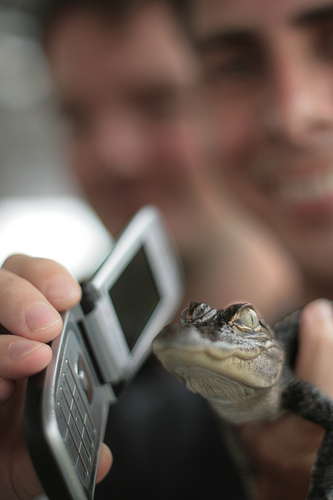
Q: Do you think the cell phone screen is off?
A: Yes, the screen is off.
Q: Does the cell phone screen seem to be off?
A: Yes, the screen is off.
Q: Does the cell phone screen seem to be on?
A: No, the screen is off.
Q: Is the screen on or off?
A: The screen is off.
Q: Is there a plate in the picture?
A: No, there are no plates.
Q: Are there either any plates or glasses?
A: No, there are no plates or glasses.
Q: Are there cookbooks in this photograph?
A: No, there are no cookbooks.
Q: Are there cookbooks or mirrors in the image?
A: No, there are no cookbooks or mirrors.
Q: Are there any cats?
A: No, there are no cats.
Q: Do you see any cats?
A: No, there are no cats.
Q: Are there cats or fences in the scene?
A: No, there are no cats or fences.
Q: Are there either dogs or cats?
A: No, there are no cats or dogs.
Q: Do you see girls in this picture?
A: No, there are no girls.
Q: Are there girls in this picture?
A: No, there are no girls.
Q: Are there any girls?
A: No, there are no girls.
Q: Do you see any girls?
A: No, there are no girls.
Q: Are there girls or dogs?
A: No, there are no girls or dogs.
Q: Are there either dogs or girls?
A: No, there are no girls or dogs.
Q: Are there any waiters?
A: No, there are no waiters.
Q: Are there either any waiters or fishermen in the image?
A: No, there are no waiters or fishermen.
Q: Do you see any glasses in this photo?
A: No, there are no glasses.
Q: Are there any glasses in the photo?
A: No, there are no glasses.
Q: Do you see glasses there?
A: No, there are no glasses.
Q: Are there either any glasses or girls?
A: No, there are no glasses or girls.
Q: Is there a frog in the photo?
A: Yes, there is a frog.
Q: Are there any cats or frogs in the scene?
A: Yes, there is a frog.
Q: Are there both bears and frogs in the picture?
A: No, there is a frog but no bears.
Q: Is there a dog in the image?
A: No, there are no dogs.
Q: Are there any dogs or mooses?
A: No, there are no dogs or mooses.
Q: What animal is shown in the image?
A: The animal is a frog.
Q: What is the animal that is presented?
A: The animal is a frog.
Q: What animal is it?
A: The animal is a frog.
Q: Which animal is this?
A: This is a frog.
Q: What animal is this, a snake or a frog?
A: This is a frog.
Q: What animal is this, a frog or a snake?
A: This is a frog.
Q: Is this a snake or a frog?
A: This is a frog.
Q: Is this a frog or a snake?
A: This is a frog.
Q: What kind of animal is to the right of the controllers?
A: The animal is a frog.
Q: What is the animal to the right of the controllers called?
A: The animal is a frog.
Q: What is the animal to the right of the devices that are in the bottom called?
A: The animal is a frog.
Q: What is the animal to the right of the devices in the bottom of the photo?
A: The animal is a frog.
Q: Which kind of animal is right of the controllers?
A: The animal is a frog.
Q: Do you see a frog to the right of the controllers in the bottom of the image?
A: Yes, there is a frog to the right of the controllers.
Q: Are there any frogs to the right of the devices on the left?
A: Yes, there is a frog to the right of the controllers.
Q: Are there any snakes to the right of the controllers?
A: No, there is a frog to the right of the controllers.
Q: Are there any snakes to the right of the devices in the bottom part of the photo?
A: No, there is a frog to the right of the controllers.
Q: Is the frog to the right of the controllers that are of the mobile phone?
A: Yes, the frog is to the right of the controllers.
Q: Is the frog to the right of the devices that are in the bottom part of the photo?
A: Yes, the frog is to the right of the controllers.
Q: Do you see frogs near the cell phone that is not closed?
A: Yes, there is a frog near the mobile phone.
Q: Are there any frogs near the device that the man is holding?
A: Yes, there is a frog near the mobile phone.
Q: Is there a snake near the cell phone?
A: No, there is a frog near the cell phone.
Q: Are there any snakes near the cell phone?
A: No, there is a frog near the cell phone.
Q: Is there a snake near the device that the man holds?
A: No, there is a frog near the cell phone.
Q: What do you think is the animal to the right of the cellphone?
A: The animal is a frog.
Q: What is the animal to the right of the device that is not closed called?
A: The animal is a frog.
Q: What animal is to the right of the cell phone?
A: The animal is a frog.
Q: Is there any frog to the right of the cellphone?
A: Yes, there is a frog to the right of the cellphone.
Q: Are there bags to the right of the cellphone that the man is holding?
A: No, there is a frog to the right of the cell phone.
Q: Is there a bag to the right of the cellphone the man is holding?
A: No, there is a frog to the right of the cell phone.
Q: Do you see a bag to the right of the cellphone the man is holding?
A: No, there is a frog to the right of the cell phone.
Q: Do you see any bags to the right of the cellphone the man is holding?
A: No, there is a frog to the right of the cell phone.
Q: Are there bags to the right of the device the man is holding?
A: No, there is a frog to the right of the cell phone.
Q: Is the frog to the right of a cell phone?
A: Yes, the frog is to the right of a cell phone.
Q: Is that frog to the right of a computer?
A: No, the frog is to the right of a cell phone.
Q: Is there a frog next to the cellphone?
A: Yes, there is a frog next to the cellphone.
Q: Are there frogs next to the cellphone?
A: Yes, there is a frog next to the cellphone.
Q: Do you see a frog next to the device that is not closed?
A: Yes, there is a frog next to the cellphone.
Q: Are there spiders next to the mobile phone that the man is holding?
A: No, there is a frog next to the mobile phone.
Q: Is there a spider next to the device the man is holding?
A: No, there is a frog next to the mobile phone.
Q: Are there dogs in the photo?
A: No, there are no dogs.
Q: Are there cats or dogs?
A: No, there are no dogs or cats.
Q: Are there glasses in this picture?
A: No, there are no glasses.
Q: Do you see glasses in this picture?
A: No, there are no glasses.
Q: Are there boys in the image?
A: No, there are no boys.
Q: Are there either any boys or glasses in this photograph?
A: No, there are no boys or glasses.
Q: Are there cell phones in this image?
A: Yes, there is a cell phone.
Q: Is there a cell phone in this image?
A: Yes, there is a cell phone.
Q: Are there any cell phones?
A: Yes, there is a cell phone.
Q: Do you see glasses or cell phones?
A: Yes, there is a cell phone.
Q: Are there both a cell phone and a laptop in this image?
A: No, there is a cell phone but no laptops.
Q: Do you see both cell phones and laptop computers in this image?
A: No, there is a cell phone but no laptops.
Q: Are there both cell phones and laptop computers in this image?
A: No, there is a cell phone but no laptops.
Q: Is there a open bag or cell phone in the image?
A: Yes, there is an open cell phone.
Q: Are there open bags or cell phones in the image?
A: Yes, there is an open cell phone.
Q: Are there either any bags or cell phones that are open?
A: Yes, the cell phone is open.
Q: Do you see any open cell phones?
A: Yes, there is an open cell phone.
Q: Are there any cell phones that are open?
A: Yes, there is a cell phone that is open.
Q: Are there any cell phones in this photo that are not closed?
A: Yes, there is a open cell phone.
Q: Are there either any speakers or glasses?
A: No, there are no glasses or speakers.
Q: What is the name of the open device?
A: The device is a cell phone.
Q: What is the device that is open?
A: The device is a cell phone.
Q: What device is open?
A: The device is a cell phone.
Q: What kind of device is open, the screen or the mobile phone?
A: The mobile phone is open.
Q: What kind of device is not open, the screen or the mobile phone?
A: The screen is not open.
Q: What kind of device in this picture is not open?
A: The device is a screen.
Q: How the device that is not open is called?
A: The device is a screen.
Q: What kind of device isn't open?
A: The device is a screen.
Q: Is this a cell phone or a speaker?
A: This is a cell phone.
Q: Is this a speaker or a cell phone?
A: This is a cell phone.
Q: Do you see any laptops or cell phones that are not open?
A: No, there is a cell phone but it is open.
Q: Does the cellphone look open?
A: Yes, the cellphone is open.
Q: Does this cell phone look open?
A: Yes, the cell phone is open.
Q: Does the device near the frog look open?
A: Yes, the cell phone is open.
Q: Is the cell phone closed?
A: No, the cell phone is open.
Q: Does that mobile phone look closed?
A: No, the mobile phone is open.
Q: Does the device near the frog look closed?
A: No, the mobile phone is open.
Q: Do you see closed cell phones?
A: No, there is a cell phone but it is open.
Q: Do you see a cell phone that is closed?
A: No, there is a cell phone but it is open.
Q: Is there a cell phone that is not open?
A: No, there is a cell phone but it is open.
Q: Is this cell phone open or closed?
A: The cell phone is open.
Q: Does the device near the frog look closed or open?
A: The cell phone is open.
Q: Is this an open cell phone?
A: Yes, this is an open cell phone.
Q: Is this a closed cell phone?
A: No, this is an open cell phone.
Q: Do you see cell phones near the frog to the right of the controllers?
A: Yes, there is a cell phone near the frog.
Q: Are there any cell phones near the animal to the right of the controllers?
A: Yes, there is a cell phone near the frog.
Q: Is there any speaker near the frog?
A: No, there is a cell phone near the frog.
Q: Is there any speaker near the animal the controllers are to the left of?
A: No, there is a cell phone near the frog.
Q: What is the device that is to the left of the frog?
A: The device is a cell phone.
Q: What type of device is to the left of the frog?
A: The device is a cell phone.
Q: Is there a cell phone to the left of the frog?
A: Yes, there is a cell phone to the left of the frog.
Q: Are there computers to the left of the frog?
A: No, there is a cell phone to the left of the frog.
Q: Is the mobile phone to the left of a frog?
A: Yes, the mobile phone is to the left of a frog.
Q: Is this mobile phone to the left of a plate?
A: No, the mobile phone is to the left of a frog.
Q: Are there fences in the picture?
A: No, there are no fences.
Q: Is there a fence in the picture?
A: No, there are no fences.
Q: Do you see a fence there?
A: No, there are no fences.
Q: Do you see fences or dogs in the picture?
A: No, there are no fences or dogs.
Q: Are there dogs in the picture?
A: No, there are no dogs.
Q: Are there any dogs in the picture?
A: No, there are no dogs.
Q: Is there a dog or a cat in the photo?
A: No, there are no dogs or cats.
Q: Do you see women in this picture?
A: No, there are no women.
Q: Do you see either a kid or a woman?
A: No, there are no women or children.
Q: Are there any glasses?
A: No, there are no glasses.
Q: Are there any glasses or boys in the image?
A: No, there are no glasses or boys.